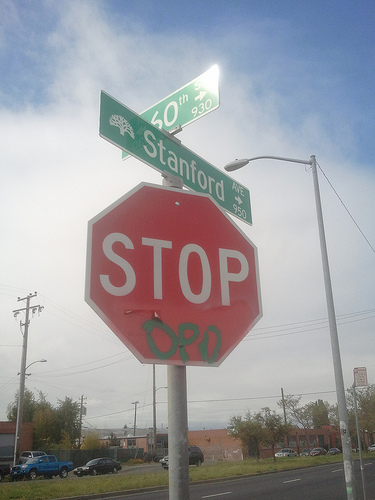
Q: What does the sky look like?
A: Cloudy.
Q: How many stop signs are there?
A: One.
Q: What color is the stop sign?
A: Red.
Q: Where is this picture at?
A: Street.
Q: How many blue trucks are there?
A: One.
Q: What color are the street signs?
A: Greens.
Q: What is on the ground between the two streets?
A: Grass.